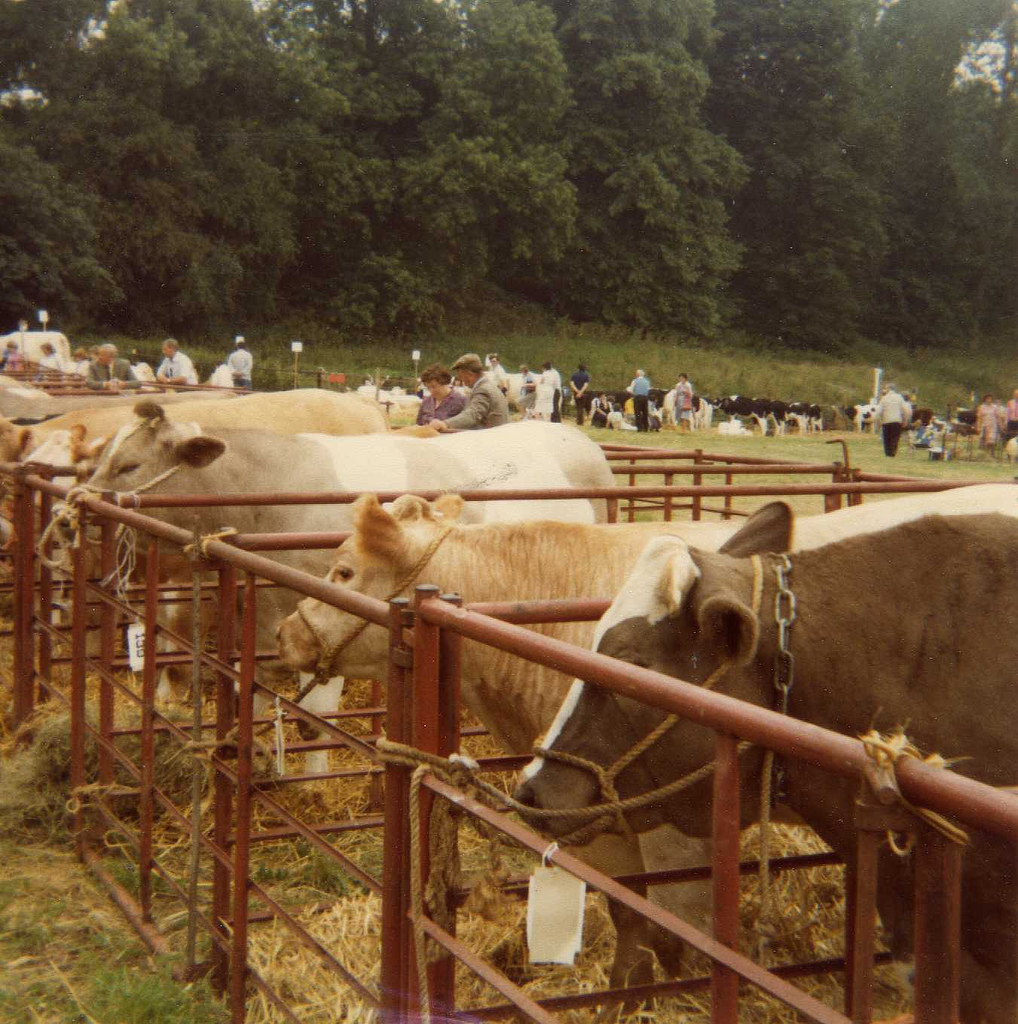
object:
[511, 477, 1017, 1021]
cow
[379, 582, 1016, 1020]
cage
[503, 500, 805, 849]
face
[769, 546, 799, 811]
chain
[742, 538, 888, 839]
neck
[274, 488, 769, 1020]
cow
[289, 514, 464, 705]
rope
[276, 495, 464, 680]
face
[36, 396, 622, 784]
cow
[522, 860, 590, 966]
tag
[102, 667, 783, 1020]
hay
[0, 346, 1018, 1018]
ground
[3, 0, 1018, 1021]
scene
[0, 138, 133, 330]
trees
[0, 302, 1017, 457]
crowd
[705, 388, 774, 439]
cows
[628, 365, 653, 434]
person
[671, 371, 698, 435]
person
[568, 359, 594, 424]
person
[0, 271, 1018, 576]
standing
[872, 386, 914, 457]
person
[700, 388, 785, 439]
cow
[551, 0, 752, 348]
trees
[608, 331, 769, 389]
hill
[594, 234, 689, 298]
grass